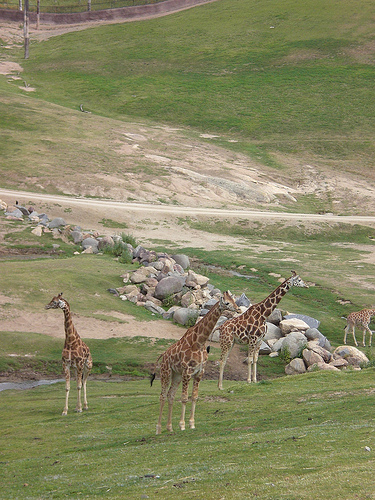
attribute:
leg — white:
[152, 407, 164, 439]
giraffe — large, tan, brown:
[41, 293, 100, 418]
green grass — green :
[8, 4, 368, 495]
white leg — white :
[165, 411, 175, 436]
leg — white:
[179, 402, 193, 433]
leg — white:
[187, 395, 197, 430]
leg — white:
[216, 360, 230, 392]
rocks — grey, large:
[273, 320, 368, 381]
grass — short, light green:
[2, 1, 370, 495]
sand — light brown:
[0, 293, 197, 342]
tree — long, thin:
[18, 0, 37, 55]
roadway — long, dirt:
[2, 184, 374, 238]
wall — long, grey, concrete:
[0, 0, 193, 28]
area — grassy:
[2, 11, 374, 493]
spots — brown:
[157, 307, 211, 386]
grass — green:
[0, 365, 369, 497]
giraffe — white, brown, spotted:
[51, 288, 94, 421]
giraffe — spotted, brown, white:
[152, 283, 244, 434]